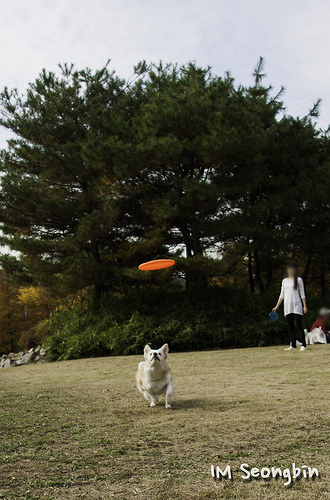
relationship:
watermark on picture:
[204, 461, 326, 484] [2, 12, 325, 499]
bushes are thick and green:
[59, 307, 108, 354] [151, 306, 177, 328]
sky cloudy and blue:
[229, 11, 285, 44] [118, 7, 176, 43]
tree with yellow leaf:
[17, 85, 123, 292] [15, 288, 40, 304]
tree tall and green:
[17, 85, 123, 292] [151, 306, 177, 328]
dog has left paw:
[138, 334, 173, 412] [165, 387, 177, 408]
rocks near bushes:
[11, 345, 45, 362] [59, 307, 108, 354]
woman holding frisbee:
[267, 261, 310, 350] [134, 254, 181, 273]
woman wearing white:
[267, 261, 310, 350] [278, 279, 304, 312]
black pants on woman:
[285, 318, 305, 343] [267, 261, 310, 350]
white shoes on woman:
[278, 279, 304, 312] [267, 261, 310, 350]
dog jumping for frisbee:
[138, 334, 173, 412] [134, 254, 181, 273]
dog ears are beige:
[138, 334, 173, 412] [146, 376, 162, 391]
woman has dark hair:
[267, 261, 310, 350] [294, 277, 297, 291]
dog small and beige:
[138, 334, 173, 412] [146, 376, 162, 391]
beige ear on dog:
[146, 376, 162, 391] [138, 334, 173, 412]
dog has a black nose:
[138, 334, 173, 412] [153, 354, 158, 359]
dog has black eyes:
[138, 334, 173, 412] [146, 349, 165, 359]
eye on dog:
[158, 348, 163, 357] [138, 334, 173, 412]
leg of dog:
[147, 392, 161, 411] [138, 334, 173, 412]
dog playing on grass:
[138, 334, 173, 412] [6, 389, 60, 452]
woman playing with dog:
[267, 261, 310, 350] [138, 334, 173, 412]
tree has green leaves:
[17, 85, 123, 292] [258, 73, 263, 81]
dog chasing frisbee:
[138, 334, 173, 412] [134, 254, 181, 273]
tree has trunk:
[17, 85, 123, 292] [248, 263, 267, 290]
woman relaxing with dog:
[267, 261, 310, 350] [138, 334, 173, 412]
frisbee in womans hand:
[269, 312, 282, 323] [302, 307, 308, 315]